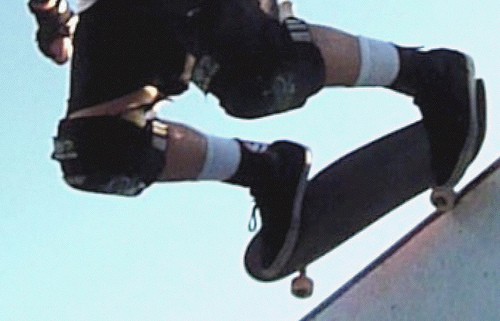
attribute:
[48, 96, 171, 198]
knee pad — black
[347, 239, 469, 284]
ramp — cement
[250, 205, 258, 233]
shoelace — black 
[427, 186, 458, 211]
wheels — white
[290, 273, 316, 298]
wheels — white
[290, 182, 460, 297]
wheels — black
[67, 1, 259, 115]
shorts — black, denim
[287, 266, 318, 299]
wheel — yellow 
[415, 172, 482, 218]
wheel — yellow 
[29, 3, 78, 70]
glove — black, open-handed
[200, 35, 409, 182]
socks — white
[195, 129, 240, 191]
sock — white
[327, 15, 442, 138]
sock — white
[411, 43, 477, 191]
shoe — Black 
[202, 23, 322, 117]
knee pad — black 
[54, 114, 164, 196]
knee pad — black 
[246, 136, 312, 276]
shoe — black, white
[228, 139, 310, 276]
shoe — black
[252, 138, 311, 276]
shoe — black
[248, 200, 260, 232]
shoe string — black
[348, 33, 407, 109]
sock — white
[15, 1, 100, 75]
wrist band — black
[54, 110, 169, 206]
knee pad — black 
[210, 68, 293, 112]
knee pad — protective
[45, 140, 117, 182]
knee pad — protective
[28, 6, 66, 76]
glove — protective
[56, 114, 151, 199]
knee — bent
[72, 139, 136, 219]
kneepad — black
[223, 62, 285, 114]
kneepad — black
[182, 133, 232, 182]
sock — white, cotton, high-top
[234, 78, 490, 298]
skateboard — black